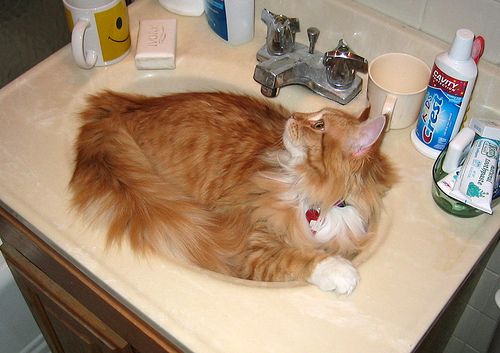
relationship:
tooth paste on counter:
[428, 24, 486, 128] [381, 222, 461, 300]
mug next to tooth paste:
[358, 45, 433, 125] [428, 24, 486, 128]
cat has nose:
[87, 78, 373, 264] [292, 103, 310, 121]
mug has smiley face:
[49, 0, 138, 66] [111, 11, 142, 49]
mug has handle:
[358, 45, 433, 125] [381, 90, 413, 129]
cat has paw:
[87, 78, 373, 264] [309, 250, 362, 292]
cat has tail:
[87, 78, 373, 264] [76, 146, 174, 235]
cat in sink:
[87, 78, 373, 264] [160, 58, 244, 105]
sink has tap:
[160, 58, 244, 105] [253, 44, 319, 96]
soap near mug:
[129, 17, 170, 62] [49, 0, 138, 66]